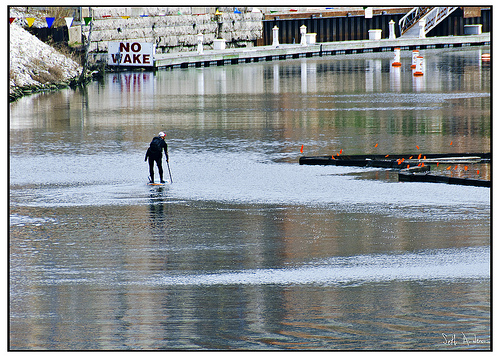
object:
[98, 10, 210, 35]
wall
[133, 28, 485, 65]
walk way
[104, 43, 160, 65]
sign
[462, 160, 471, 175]
flags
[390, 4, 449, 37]
ramp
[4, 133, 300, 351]
water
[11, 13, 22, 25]
colored flags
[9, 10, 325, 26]
rope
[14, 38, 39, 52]
snow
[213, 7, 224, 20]
flags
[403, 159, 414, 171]
orange flags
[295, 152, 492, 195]
divider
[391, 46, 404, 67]
barrels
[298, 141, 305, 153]
buoy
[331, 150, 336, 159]
buoy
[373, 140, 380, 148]
buoy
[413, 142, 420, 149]
buoy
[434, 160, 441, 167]
buoy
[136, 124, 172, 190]
man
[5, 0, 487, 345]
daytime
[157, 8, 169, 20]
flags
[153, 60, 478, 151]
water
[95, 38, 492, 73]
edging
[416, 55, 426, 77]
barrels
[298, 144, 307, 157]
flag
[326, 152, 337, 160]
flag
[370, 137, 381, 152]
flag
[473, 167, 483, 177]
flag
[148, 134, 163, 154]
backpack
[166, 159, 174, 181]
stick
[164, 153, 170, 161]
hand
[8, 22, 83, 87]
sloped edge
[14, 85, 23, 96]
plants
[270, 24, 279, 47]
post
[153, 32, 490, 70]
dock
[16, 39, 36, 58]
ground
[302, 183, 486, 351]
water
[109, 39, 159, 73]
no wake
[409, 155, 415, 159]
flag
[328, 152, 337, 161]
flag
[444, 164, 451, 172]
flag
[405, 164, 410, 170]
flag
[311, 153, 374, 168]
border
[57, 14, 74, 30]
flag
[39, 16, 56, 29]
flag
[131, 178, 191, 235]
reflection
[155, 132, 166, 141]
hat